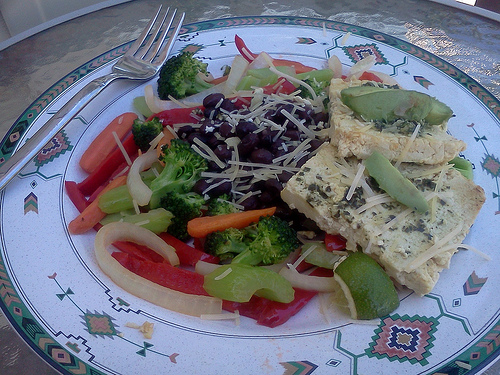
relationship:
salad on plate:
[195, 108, 336, 208] [52, 21, 496, 326]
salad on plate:
[66, 49, 486, 326] [0, 14, 497, 373]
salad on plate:
[141, 75, 451, 262] [0, 14, 497, 373]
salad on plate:
[158, 129, 328, 276] [0, 14, 497, 373]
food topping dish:
[64, 37, 485, 310] [67, 51, 484, 336]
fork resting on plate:
[1, 0, 185, 186] [0, 14, 497, 373]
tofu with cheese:
[282, 78, 486, 295] [187, 83, 492, 274]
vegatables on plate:
[64, 35, 477, 322] [0, 14, 497, 373]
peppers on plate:
[76, 142, 323, 339] [0, 14, 497, 373]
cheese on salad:
[214, 82, 340, 196] [42, 44, 482, 334]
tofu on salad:
[273, 134, 494, 304] [66, 49, 486, 326]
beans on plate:
[199, 96, 316, 193] [0, 14, 497, 373]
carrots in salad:
[63, 109, 140, 234] [66, 49, 486, 326]